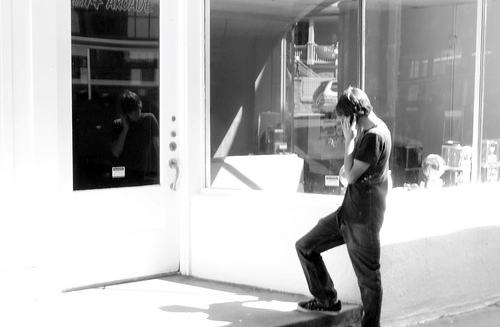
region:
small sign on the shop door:
[110, 165, 126, 180]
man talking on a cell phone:
[327, 98, 391, 320]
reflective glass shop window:
[216, 12, 497, 180]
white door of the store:
[55, 5, 183, 280]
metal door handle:
[166, 140, 180, 192]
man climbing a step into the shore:
[320, 94, 387, 322]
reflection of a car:
[308, 75, 341, 118]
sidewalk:
[407, 300, 495, 323]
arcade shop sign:
[75, 0, 157, 28]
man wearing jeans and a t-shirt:
[316, 89, 393, 310]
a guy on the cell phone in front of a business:
[0, 0, 497, 320]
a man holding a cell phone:
[344, 109, 366, 125]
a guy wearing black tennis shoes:
[280, 82, 402, 324]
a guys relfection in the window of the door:
[88, 88, 161, 180]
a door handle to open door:
[161, 147, 186, 196]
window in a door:
[72, 4, 162, 183]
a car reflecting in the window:
[308, 67, 338, 111]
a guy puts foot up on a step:
[246, 288, 373, 325]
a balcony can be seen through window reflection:
[283, 42, 355, 67]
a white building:
[0, 0, 497, 302]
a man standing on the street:
[270, 71, 417, 325]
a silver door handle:
[158, 103, 189, 197]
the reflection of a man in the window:
[100, 62, 166, 181]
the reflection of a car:
[304, 76, 354, 126]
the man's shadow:
[147, 261, 279, 322]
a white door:
[26, 3, 208, 300]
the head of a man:
[310, 69, 399, 149]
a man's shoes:
[287, 277, 346, 318]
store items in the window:
[412, 134, 497, 196]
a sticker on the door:
[99, 155, 133, 187]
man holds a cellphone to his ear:
[295, 87, 396, 325]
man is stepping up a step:
[287, 82, 392, 324]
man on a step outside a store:
[14, 3, 496, 325]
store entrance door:
[47, 4, 192, 287]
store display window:
[209, 6, 499, 197]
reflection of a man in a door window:
[104, 87, 160, 186]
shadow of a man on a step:
[162, 291, 307, 324]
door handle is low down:
[169, 152, 181, 200]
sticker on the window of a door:
[107, 164, 127, 179]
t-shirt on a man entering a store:
[335, 119, 393, 225]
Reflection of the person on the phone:
[102, 73, 159, 175]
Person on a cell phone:
[310, 80, 409, 325]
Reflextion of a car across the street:
[291, 47, 343, 113]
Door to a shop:
[5, 9, 187, 234]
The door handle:
[165, 153, 192, 199]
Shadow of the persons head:
[163, 279, 200, 324]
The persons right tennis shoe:
[286, 286, 340, 315]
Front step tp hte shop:
[292, 287, 356, 325]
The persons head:
[322, 78, 379, 123]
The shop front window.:
[364, 5, 494, 185]